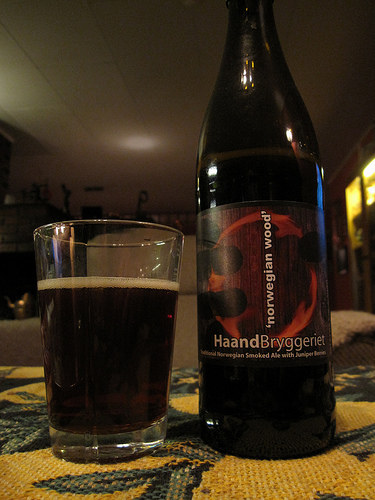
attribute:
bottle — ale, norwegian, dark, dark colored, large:
[184, 2, 340, 464]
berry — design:
[197, 239, 247, 329]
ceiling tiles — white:
[2, 2, 374, 156]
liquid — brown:
[30, 272, 177, 439]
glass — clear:
[30, 215, 185, 467]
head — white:
[47, 272, 173, 290]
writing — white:
[205, 332, 329, 353]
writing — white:
[257, 209, 281, 328]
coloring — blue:
[23, 462, 216, 497]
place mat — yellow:
[3, 364, 363, 496]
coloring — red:
[204, 205, 323, 342]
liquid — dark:
[39, 275, 174, 429]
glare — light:
[193, 413, 221, 424]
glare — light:
[47, 222, 73, 237]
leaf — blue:
[24, 469, 152, 491]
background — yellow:
[1, 377, 358, 498]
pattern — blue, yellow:
[0, 382, 248, 498]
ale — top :
[36, 289, 175, 424]